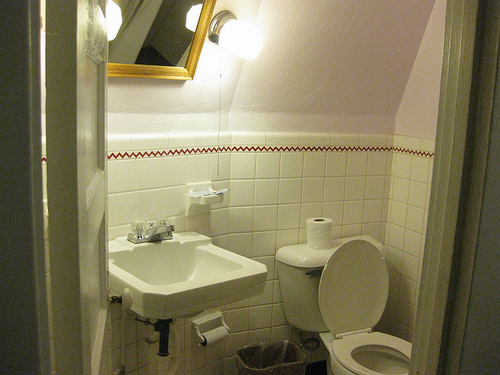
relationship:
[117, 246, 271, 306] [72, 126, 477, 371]
sink in bathroom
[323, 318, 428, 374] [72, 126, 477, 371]
toilet in bathroom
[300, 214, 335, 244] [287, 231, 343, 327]
toilet paper on tank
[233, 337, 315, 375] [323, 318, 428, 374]
garbage can by toilet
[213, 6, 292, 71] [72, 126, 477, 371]
light in bathroom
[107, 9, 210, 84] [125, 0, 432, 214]
mirror on wall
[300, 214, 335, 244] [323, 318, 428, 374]
toilet paper on toilet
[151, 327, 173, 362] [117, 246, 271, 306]
pipe under sink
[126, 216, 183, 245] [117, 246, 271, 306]
faucet over sink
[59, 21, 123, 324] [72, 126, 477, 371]
door of bathroom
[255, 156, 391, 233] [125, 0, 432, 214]
tile one wall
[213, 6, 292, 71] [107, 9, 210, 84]
light by mirror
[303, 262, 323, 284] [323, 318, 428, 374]
handle on toilet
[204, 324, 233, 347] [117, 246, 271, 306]
roll under sink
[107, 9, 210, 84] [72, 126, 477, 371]
mirror in bathroom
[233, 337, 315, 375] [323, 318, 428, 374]
wastse basket by toilet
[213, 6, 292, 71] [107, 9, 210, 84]
light near mirror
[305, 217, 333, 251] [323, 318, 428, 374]
toilet paper on toilet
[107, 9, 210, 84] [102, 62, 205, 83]
mirror has frame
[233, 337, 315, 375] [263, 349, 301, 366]
garbage can has bag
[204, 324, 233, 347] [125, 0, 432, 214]
roll on wall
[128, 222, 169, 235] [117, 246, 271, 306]
fixtures on sink